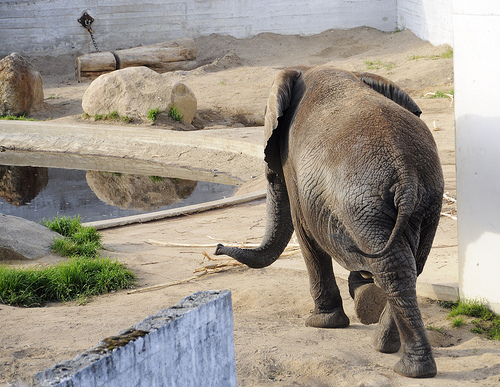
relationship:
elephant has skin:
[212, 70, 461, 376] [310, 90, 434, 272]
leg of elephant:
[366, 236, 456, 381] [212, 70, 461, 376]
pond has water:
[41, 161, 149, 243] [11, 141, 227, 234]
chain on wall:
[83, 12, 105, 41] [120, 9, 333, 28]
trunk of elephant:
[211, 166, 296, 289] [212, 70, 461, 376]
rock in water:
[76, 64, 192, 152] [11, 141, 227, 234]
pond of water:
[41, 161, 149, 243] [11, 141, 227, 234]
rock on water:
[76, 64, 192, 152] [11, 141, 227, 234]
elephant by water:
[212, 70, 461, 376] [11, 141, 227, 234]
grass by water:
[4, 267, 161, 310] [11, 141, 227, 234]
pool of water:
[4, 104, 290, 248] [11, 141, 227, 234]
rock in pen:
[76, 64, 192, 152] [4, 1, 449, 377]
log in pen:
[63, 42, 211, 72] [4, 1, 449, 377]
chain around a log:
[83, 12, 105, 41] [72, 39, 209, 74]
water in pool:
[11, 141, 227, 234] [4, 110, 286, 240]